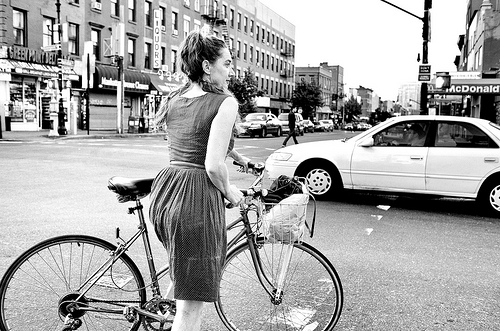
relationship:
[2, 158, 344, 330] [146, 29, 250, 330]
bicycle of woman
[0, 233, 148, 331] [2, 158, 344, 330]
wheel of bicycle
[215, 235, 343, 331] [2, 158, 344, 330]
wheel of bicycle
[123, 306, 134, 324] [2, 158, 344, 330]
pedal of bicycle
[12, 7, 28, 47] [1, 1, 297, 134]
window in building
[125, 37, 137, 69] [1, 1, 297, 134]
window in building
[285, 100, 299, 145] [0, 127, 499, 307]
man in street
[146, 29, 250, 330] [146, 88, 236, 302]
woman in dress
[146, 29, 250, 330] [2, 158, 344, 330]
woman with bicycle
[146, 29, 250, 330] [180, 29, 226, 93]
woman with hair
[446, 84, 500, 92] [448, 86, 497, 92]
mcdonalds of mcdonalds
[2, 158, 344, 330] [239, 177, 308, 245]
bicycle with basket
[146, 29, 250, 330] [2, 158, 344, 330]
woman walking bicycle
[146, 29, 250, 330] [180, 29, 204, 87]
woman with ponytail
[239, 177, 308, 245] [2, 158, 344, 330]
basket on bicycle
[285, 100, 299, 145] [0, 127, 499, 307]
man crossing street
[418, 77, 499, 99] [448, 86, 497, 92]
awning of mcdonalds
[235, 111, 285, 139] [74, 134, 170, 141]
car along curb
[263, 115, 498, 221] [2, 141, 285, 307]
car crossing intersection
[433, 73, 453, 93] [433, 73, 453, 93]
stoplight with stoplight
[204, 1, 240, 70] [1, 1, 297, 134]
fire escape on building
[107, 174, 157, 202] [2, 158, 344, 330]
seat on bicycle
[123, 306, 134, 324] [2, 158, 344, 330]
pedal on bicycle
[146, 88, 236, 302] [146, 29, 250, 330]
dress on woman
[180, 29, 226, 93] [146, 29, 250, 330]
hair on woman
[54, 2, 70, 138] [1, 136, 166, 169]
pole by road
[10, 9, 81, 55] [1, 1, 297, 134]
windows on building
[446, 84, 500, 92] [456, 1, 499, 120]
mcdonalds on building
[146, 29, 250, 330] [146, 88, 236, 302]
woman wearing dress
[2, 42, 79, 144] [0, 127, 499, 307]
deli across street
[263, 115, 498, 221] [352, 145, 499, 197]
car has doors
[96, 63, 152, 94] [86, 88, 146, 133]
awning over storefront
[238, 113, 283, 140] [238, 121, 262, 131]
car with headlights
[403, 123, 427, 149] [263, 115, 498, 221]
man driving car